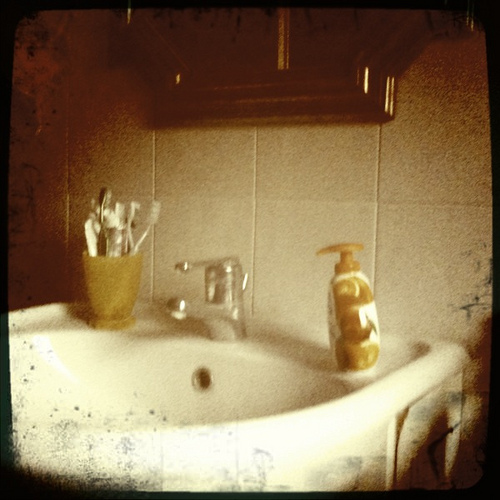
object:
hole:
[192, 369, 213, 393]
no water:
[12, 335, 354, 433]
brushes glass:
[82, 254, 138, 330]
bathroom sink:
[0, 306, 465, 495]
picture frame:
[95, 9, 397, 127]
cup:
[82, 251, 143, 331]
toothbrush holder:
[81, 246, 144, 329]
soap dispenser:
[316, 243, 381, 370]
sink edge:
[266, 429, 343, 473]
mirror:
[123, 12, 396, 119]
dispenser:
[315, 237, 381, 376]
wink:
[43, 291, 403, 495]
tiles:
[377, 214, 491, 334]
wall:
[6, 10, 498, 453]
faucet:
[167, 257, 250, 340]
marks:
[454, 246, 499, 327]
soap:
[314, 242, 380, 367]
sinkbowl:
[17, 333, 352, 427]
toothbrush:
[135, 201, 160, 252]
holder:
[78, 242, 141, 329]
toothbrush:
[121, 199, 138, 253]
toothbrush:
[98, 186, 110, 254]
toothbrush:
[115, 200, 129, 254]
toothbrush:
[99, 209, 120, 256]